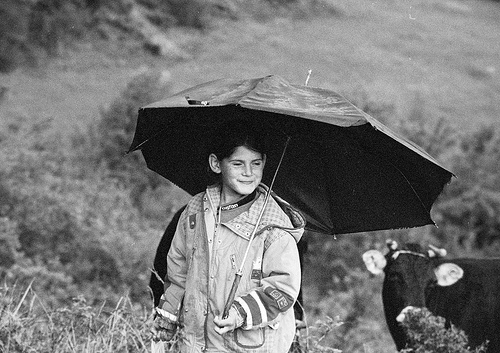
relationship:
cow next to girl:
[363, 241, 500, 350] [157, 113, 300, 353]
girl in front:
[157, 113, 300, 353] [3, 146, 500, 349]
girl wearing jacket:
[157, 113, 300, 353] [156, 188, 303, 352]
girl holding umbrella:
[157, 113, 300, 353] [133, 67, 459, 238]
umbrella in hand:
[133, 67, 459, 238] [212, 300, 247, 334]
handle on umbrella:
[220, 272, 241, 318] [133, 67, 459, 238]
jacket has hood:
[156, 188, 303, 352] [202, 185, 310, 240]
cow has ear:
[363, 241, 500, 350] [436, 259, 468, 296]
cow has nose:
[363, 241, 500, 350] [392, 302, 431, 329]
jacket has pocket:
[156, 188, 303, 352] [233, 325, 270, 350]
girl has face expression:
[157, 113, 300, 353] [222, 149, 270, 192]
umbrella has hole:
[133, 67, 459, 238] [186, 96, 221, 114]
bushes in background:
[1, 71, 497, 278] [2, 2, 499, 243]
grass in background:
[8, 1, 499, 130] [2, 2, 499, 243]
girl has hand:
[157, 113, 300, 353] [212, 300, 247, 334]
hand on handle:
[212, 300, 247, 334] [220, 272, 241, 318]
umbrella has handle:
[133, 67, 459, 238] [220, 272, 241, 318]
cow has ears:
[363, 241, 500, 350] [361, 245, 465, 285]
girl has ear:
[157, 113, 300, 353] [206, 150, 221, 175]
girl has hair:
[157, 113, 300, 353] [207, 121, 273, 158]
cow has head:
[363, 241, 500, 350] [358, 233, 466, 328]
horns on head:
[382, 236, 451, 258] [358, 233, 466, 328]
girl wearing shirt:
[157, 113, 300, 353] [217, 195, 263, 223]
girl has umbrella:
[157, 113, 300, 353] [133, 67, 459, 238]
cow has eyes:
[363, 241, 500, 350] [388, 268, 446, 288]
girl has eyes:
[157, 113, 300, 353] [225, 156, 266, 170]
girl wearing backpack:
[157, 113, 300, 353] [291, 223, 313, 320]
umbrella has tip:
[133, 67, 459, 238] [299, 64, 319, 90]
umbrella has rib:
[133, 67, 459, 238] [361, 139, 449, 230]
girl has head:
[157, 113, 300, 353] [203, 119, 271, 198]